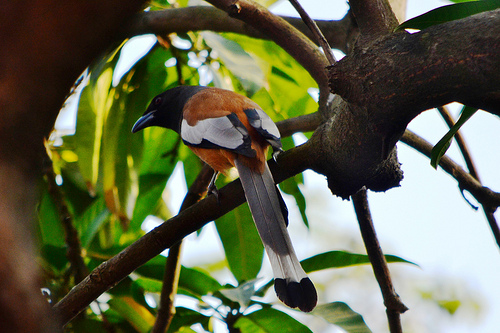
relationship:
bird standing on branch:
[132, 83, 320, 310] [53, 127, 323, 323]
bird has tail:
[132, 83, 320, 310] [234, 157, 318, 315]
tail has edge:
[234, 157, 318, 315] [275, 275, 317, 312]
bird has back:
[132, 83, 320, 310] [184, 84, 260, 120]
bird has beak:
[132, 83, 320, 310] [128, 111, 152, 134]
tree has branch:
[0, 0, 500, 333] [54, 150, 309, 307]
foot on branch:
[194, 181, 224, 214] [54, 150, 309, 307]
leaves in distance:
[142, 204, 392, 327] [105, 112, 496, 331]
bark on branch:
[337, 40, 492, 128] [248, 13, 498, 189]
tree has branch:
[213, 0, 493, 263] [248, 13, 498, 189]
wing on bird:
[182, 111, 253, 162] [132, 83, 320, 310]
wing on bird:
[243, 97, 283, 153] [132, 83, 320, 310]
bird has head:
[132, 83, 320, 310] [134, 83, 189, 132]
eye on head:
[151, 97, 165, 109] [134, 83, 189, 132]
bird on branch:
[132, 83, 320, 310] [63, 145, 318, 309]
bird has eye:
[132, 83, 320, 310] [148, 94, 171, 118]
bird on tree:
[132, 83, 320, 310] [7, 6, 499, 331]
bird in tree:
[132, 83, 320, 310] [7, 6, 499, 331]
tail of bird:
[234, 157, 318, 315] [132, 83, 320, 310]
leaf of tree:
[191, 163, 268, 302] [7, 6, 499, 331]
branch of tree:
[248, 13, 498, 189] [7, 6, 499, 331]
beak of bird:
[127, 107, 157, 137] [122, 78, 327, 315]